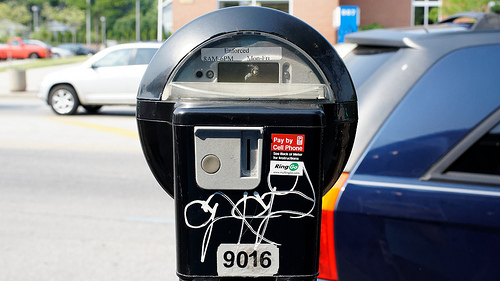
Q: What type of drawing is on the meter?
A: Graffitti.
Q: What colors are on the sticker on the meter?
A: Red, white, green and black.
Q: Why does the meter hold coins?
A: Pay for parking.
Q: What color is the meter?
A: Black.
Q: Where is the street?
A: Behind the meter and car.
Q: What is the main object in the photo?
A: Parking meter.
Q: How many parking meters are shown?
A: One.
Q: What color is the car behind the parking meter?
A: Blue.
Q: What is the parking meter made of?
A: Metal.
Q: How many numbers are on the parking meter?
A: Four.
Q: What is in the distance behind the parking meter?
A: A building.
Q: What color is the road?
A: Grey.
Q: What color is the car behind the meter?
A: White.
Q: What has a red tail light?
A: The blue car.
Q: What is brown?
A: The building.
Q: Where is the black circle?
A: On top of the parking meter.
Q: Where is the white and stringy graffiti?
A: On the meter.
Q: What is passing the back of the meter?
A: A white car.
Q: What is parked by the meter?
A: A blue car.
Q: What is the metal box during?
A: Supporting the top of the meter.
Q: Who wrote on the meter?
A: Vandals.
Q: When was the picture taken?
A: Daytime.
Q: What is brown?
A: Building.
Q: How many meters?
A: One.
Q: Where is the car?
A: To the right of the meter.